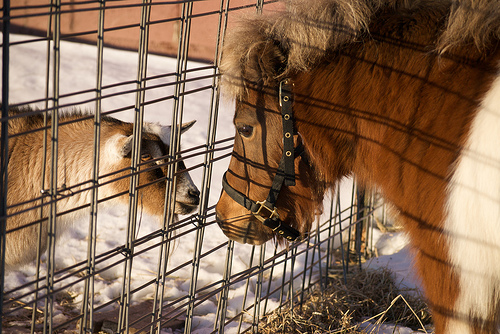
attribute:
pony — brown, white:
[208, 0, 498, 333]